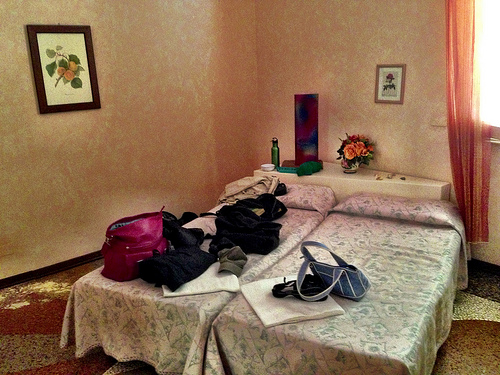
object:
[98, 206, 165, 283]
bag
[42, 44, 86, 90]
flowers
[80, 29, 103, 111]
frame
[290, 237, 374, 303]
bag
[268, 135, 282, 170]
bottle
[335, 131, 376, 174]
vase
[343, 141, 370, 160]
flowers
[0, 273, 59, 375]
floor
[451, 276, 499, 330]
design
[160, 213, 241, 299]
clothes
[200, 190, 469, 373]
bed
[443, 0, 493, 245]
curtains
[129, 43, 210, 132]
wallpaper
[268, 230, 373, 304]
purse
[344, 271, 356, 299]
white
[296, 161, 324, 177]
hat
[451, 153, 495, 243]
drapes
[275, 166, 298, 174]
item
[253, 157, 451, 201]
table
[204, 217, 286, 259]
bag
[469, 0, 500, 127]
window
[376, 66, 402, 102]
picture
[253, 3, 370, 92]
wall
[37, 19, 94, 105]
picture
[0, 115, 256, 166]
wall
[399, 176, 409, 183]
rocks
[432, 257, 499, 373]
carpet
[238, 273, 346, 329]
towel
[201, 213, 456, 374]
bedspread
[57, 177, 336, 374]
bed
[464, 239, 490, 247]
lace